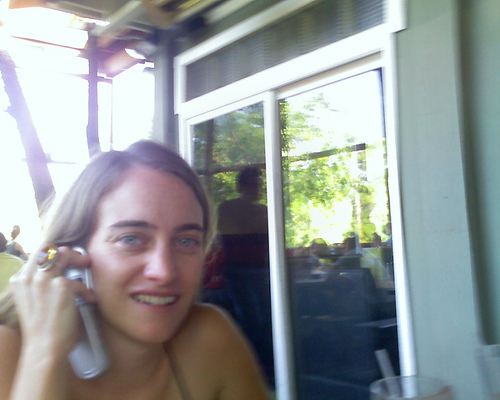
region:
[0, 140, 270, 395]
a young woman holding a phone to her ear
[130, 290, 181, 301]
white teeth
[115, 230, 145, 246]
pale blue eyes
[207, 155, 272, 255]
a man's reflection on a sliding glass door in the background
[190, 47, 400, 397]
a sliding glass door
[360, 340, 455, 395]
a drink with a straw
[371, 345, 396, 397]
a drinking straw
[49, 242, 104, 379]
a portable phone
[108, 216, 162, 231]
a brown eyebrow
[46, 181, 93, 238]
light brown hair back-lit with sunlight streaming through it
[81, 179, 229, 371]
one lady is seen.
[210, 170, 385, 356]
Reflection is seen in door.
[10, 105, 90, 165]
Day time picture.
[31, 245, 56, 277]
lady is wearing a ring in her fingers.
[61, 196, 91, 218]
hair is grey color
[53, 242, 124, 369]
lady is holding white color object.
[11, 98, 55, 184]
Woods are brown color.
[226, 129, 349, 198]
trees are green color.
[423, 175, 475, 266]
Wall is grey color.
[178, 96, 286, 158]
Frame is white color.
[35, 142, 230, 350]
a woman with light colored eyes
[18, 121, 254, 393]
a girl with light colored hair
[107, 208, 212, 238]
a pair of dark eyebrows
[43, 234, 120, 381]
a silver flip phone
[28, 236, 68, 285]
a very large, amber ring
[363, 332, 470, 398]
a glass with a straw in it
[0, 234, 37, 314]
person in light colored shirt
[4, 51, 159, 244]
two tree trunks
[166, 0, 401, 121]
a rectangular vent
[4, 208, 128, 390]
The girl is holding a phone.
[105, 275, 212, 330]
The girl is smiling.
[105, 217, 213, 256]
The girl has blue eyes.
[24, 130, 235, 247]
The girl has blonde hair.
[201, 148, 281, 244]
A person is reflected in the window.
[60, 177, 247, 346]
The girl is looking at the camera.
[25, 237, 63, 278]
The girl is wearing a ring.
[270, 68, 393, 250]
Trees are reflected in the window.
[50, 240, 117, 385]
The phone is silver.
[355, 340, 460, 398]
A glass and straw are next to the girl.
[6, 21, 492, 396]
young woman talking on a cell phone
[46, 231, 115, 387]
silver flip phone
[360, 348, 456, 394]
clear drinking glass with straw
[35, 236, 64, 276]
Large amber ring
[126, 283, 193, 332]
open mouthed smile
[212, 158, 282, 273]
man reflected in window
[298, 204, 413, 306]
people eating reflected in window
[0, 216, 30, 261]
blonde woman facing away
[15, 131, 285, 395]
lady chatting on phone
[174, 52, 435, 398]
sliding glass doors